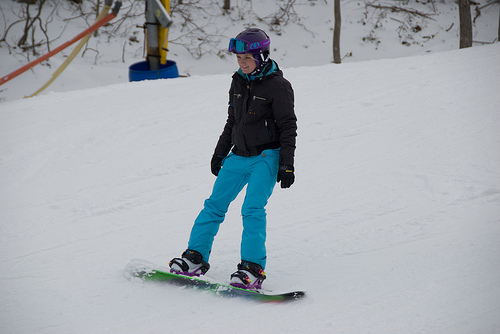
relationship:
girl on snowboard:
[198, 23, 294, 105] [135, 253, 319, 307]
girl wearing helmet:
[198, 23, 294, 105] [234, 28, 269, 57]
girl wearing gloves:
[198, 23, 294, 105] [207, 154, 301, 191]